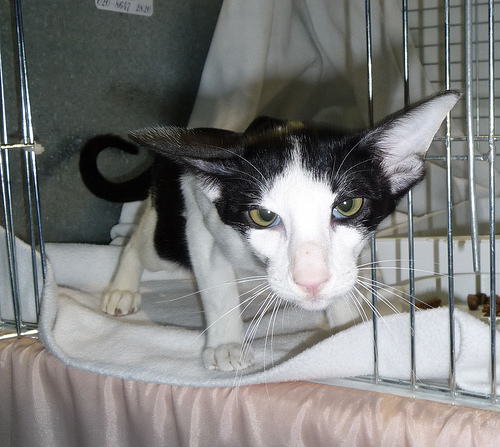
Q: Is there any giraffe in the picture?
A: No, there are no giraffes.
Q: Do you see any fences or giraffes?
A: No, there are no giraffes or fences.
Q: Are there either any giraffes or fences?
A: No, there are no giraffes or fences.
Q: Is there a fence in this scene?
A: No, there are no fences.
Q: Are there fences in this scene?
A: No, there are no fences.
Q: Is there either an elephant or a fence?
A: No, there are no fences or elephants.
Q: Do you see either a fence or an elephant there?
A: No, there are no fences or elephants.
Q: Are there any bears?
A: No, there are no bears.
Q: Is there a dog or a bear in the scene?
A: No, there are no bears or dogs.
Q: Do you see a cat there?
A: Yes, there is a cat.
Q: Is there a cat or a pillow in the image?
A: Yes, there is a cat.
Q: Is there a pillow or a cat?
A: Yes, there is a cat.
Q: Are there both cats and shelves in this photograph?
A: No, there is a cat but no shelves.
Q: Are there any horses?
A: No, there are no horses.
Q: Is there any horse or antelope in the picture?
A: No, there are no horses or antelopes.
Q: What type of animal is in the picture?
A: The animal is a cat.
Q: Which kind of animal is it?
A: The animal is a cat.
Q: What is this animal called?
A: This is a cat.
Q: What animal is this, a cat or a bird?
A: This is a cat.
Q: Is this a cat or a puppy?
A: This is a cat.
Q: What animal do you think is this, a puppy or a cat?
A: This is a cat.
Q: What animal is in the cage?
A: The cat is in the cage.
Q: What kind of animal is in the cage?
A: The animal is a cat.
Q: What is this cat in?
A: The cat is in the cage.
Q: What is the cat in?
A: The cat is in the cage.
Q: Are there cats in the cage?
A: Yes, there is a cat in the cage.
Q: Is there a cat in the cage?
A: Yes, there is a cat in the cage.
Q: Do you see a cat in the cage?
A: Yes, there is a cat in the cage.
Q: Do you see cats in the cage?
A: Yes, there is a cat in the cage.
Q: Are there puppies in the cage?
A: No, there is a cat in the cage.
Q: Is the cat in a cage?
A: Yes, the cat is in a cage.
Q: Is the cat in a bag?
A: No, the cat is in a cage.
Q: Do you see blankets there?
A: Yes, there is a blanket.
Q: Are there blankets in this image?
A: Yes, there is a blanket.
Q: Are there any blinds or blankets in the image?
A: Yes, there is a blanket.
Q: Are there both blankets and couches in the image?
A: No, there is a blanket but no couches.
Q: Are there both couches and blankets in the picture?
A: No, there is a blanket but no couches.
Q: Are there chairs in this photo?
A: No, there are no chairs.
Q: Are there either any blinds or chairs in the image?
A: No, there are no chairs or blinds.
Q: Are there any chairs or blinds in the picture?
A: No, there are no chairs or blinds.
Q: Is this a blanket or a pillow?
A: This is a blanket.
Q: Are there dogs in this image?
A: No, there are no dogs.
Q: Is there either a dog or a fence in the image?
A: No, there are no dogs or fences.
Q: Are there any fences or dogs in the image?
A: No, there are no dogs or fences.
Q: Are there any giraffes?
A: No, there are no giraffes.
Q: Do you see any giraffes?
A: No, there are no giraffes.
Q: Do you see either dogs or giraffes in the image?
A: No, there are no giraffes or dogs.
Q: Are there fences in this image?
A: No, there are no fences.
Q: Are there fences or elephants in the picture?
A: No, there are no fences or elephants.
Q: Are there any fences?
A: No, there are no fences.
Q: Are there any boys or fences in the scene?
A: No, there are no fences or boys.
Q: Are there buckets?
A: No, there are no buckets.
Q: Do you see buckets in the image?
A: No, there are no buckets.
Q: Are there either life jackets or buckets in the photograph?
A: No, there are no buckets or life jackets.